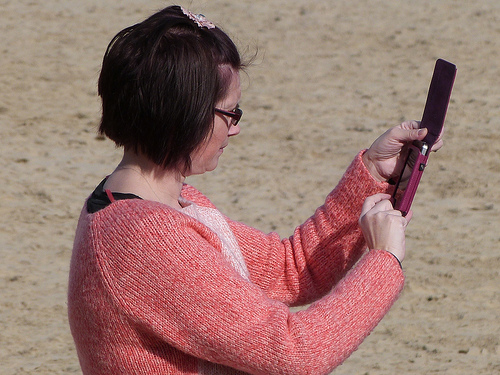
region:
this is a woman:
[88, 73, 255, 238]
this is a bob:
[109, 7, 246, 170]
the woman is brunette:
[89, 0, 175, 82]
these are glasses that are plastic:
[208, 93, 273, 148]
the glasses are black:
[197, 95, 284, 136]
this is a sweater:
[131, 203, 267, 268]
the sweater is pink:
[107, 240, 282, 355]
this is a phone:
[348, 147, 461, 223]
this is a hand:
[358, 174, 458, 299]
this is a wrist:
[333, 111, 495, 238]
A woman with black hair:
[87, 3, 275, 169]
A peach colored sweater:
[42, 175, 399, 347]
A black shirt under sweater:
[82, 171, 134, 206]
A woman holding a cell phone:
[368, 99, 459, 233]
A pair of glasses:
[216, 101, 249, 131]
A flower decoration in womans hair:
[176, 0, 226, 40]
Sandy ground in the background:
[281, 22, 372, 144]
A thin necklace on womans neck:
[114, 159, 186, 216]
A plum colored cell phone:
[383, 140, 445, 225]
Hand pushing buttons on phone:
[348, 183, 419, 263]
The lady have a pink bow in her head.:
[178, 8, 217, 31]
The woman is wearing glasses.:
[207, 100, 267, 122]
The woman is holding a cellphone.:
[383, 28, 455, 237]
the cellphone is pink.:
[393, 59, 472, 224]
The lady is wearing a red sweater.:
[48, 217, 360, 354]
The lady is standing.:
[88, 3, 315, 331]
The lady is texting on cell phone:
[101, 10, 461, 260]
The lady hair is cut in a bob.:
[99, 23, 191, 169]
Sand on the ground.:
[242, 41, 400, 152]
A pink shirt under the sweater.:
[195, 203, 248, 268]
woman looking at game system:
[52, 1, 481, 369]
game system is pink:
[369, 45, 469, 221]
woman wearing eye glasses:
[200, 98, 250, 130]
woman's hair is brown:
[86, 3, 237, 173]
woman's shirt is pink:
[61, 155, 417, 373]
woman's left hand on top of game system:
[358, 100, 438, 178]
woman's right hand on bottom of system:
[349, 179, 442, 273]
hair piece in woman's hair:
[177, 3, 222, 47]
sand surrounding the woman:
[0, 0, 496, 369]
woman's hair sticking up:
[230, 31, 267, 90]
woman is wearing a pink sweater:
[65, 5, 457, 372]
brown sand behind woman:
[1, 1, 498, 373]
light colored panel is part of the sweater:
[181, 195, 251, 278]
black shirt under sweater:
[85, 175, 140, 215]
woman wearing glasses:
[213, 104, 244, 125]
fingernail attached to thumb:
[417, 128, 424, 133]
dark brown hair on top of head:
[94, 5, 244, 177]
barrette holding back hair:
[181, 7, 218, 30]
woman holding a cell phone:
[68, 5, 458, 372]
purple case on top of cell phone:
[389, 58, 455, 214]